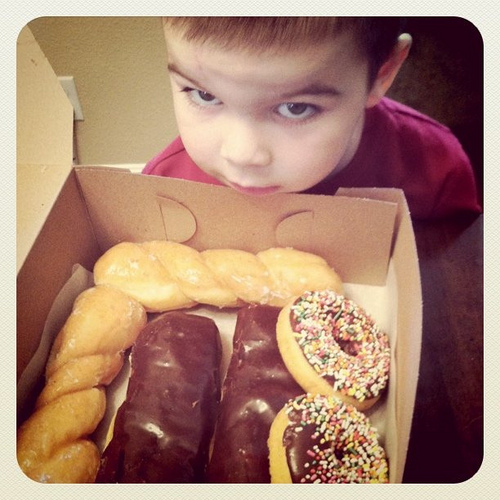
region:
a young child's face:
[133, 23, 465, 222]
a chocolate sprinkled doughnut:
[275, 291, 387, 405]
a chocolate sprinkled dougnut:
[268, 387, 387, 491]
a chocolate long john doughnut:
[109, 311, 214, 481]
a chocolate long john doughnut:
[215, 300, 297, 482]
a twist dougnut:
[90, 245, 335, 307]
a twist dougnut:
[23, 279, 128, 488]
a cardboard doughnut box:
[20, 31, 423, 477]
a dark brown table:
[394, 205, 477, 480]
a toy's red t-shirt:
[108, 101, 485, 209]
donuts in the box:
[77, 255, 377, 440]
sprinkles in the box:
[303, 292, 384, 387]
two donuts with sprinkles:
[307, 308, 407, 449]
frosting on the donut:
[230, 343, 289, 423]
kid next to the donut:
[156, 41, 352, 173]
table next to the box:
[423, 273, 468, 329]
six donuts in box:
[58, 246, 388, 461]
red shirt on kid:
[362, 107, 465, 180]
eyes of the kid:
[161, 66, 337, 134]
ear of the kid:
[368, 35, 431, 96]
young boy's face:
[164, 22, 421, 195]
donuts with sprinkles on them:
[274, 284, 416, 487]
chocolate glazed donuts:
[119, 294, 301, 479]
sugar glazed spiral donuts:
[92, 228, 353, 307]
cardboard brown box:
[29, 139, 451, 435]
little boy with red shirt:
[136, 92, 493, 292]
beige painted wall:
[67, 23, 174, 135]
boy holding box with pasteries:
[29, 22, 471, 493]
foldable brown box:
[22, 86, 457, 432]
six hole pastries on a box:
[37, 185, 420, 491]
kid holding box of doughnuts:
[129, 24, 448, 371]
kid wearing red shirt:
[392, 116, 464, 186]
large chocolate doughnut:
[147, 316, 207, 486]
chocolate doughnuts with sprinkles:
[294, 302, 363, 396]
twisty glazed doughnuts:
[108, 245, 345, 305]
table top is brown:
[447, 251, 474, 354]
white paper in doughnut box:
[360, 283, 400, 306]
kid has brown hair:
[240, 28, 335, 74]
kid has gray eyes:
[272, 75, 323, 143]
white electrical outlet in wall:
[44, 85, 97, 117]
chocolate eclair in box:
[128, 311, 227, 495]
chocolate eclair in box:
[214, 293, 304, 497]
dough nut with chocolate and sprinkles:
[258, 380, 404, 495]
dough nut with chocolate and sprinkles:
[285, 291, 392, 401]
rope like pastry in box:
[104, 232, 354, 309]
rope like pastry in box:
[61, 285, 122, 486]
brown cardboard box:
[6, 208, 426, 477]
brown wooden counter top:
[396, 212, 481, 471]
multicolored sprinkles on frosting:
[302, 417, 361, 497]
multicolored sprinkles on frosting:
[302, 288, 379, 369]